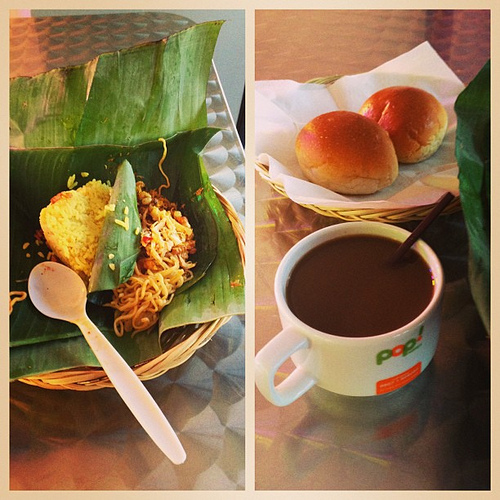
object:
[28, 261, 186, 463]
spoon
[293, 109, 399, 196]
buns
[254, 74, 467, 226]
basket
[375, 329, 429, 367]
logo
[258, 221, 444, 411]
mug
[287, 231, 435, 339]
coffee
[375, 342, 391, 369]
letters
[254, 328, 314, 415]
handle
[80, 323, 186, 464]
handle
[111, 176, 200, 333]
noodles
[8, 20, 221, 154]
leave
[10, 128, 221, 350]
leave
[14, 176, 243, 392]
basket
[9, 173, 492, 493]
table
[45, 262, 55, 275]
food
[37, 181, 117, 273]
cronbread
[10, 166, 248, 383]
leave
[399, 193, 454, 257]
straw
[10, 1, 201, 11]
edge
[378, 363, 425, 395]
writing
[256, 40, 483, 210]
cloth